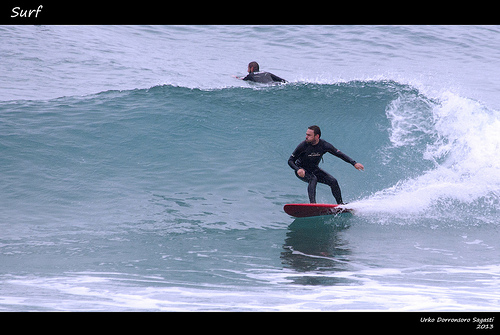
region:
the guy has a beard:
[284, 125, 336, 147]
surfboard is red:
[279, 194, 342, 224]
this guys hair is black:
[242, 56, 267, 73]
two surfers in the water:
[223, 58, 364, 258]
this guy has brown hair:
[294, 117, 336, 153]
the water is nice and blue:
[3, 25, 498, 311]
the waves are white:
[348, 75, 497, 227]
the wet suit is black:
[280, 111, 356, 211]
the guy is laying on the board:
[234, 59, 288, 91]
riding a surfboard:
[289, 100, 359, 245]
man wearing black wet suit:
[265, 114, 355, 220]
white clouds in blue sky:
[22, 43, 96, 100]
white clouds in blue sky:
[14, 114, 69, 158]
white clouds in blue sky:
[80, 137, 173, 208]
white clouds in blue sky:
[386, 91, 455, 165]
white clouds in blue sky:
[387, 164, 440, 241]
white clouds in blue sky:
[86, 245, 157, 271]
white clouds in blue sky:
[140, 189, 230, 258]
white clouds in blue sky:
[186, 213, 239, 270]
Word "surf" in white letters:
[10, 1, 45, 23]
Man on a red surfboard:
[275, 123, 371, 223]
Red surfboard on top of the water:
[277, 196, 352, 225]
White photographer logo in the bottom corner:
[418, 313, 498, 333]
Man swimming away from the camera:
[227, 55, 289, 91]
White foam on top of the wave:
[365, 72, 498, 229]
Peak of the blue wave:
[4, 73, 444, 112]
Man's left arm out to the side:
[330, 143, 372, 175]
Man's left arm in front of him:
[229, 69, 251, 89]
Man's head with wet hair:
[302, 126, 319, 141]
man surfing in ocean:
[269, 107, 362, 221]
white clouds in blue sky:
[29, 64, 95, 133]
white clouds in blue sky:
[19, 187, 72, 237]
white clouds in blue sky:
[70, 223, 150, 283]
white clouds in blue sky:
[369, 198, 427, 269]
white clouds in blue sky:
[105, 109, 182, 185]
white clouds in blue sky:
[170, 156, 241, 235]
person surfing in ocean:
[280, 125, 343, 227]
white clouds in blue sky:
[49, 244, 116, 295]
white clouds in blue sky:
[123, 225, 207, 287]